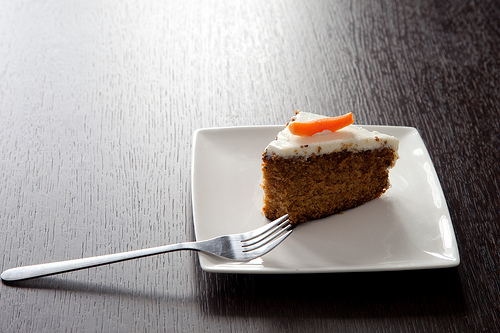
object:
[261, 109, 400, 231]
cake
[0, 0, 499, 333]
table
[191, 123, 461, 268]
plate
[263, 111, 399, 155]
icing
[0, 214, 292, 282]
fork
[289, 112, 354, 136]
carrot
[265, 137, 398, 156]
crumbs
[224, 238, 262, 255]
light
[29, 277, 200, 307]
shadow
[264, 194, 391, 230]
crust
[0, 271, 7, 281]
edge